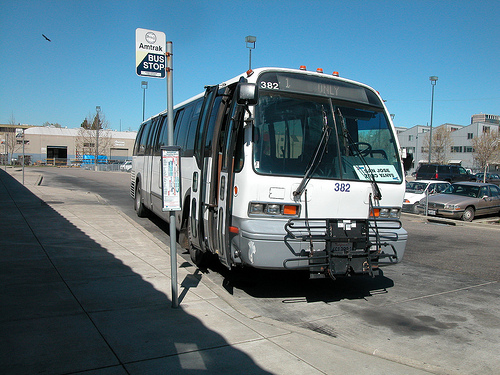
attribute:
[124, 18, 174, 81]
sign — black, white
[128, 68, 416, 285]
bus — white, parked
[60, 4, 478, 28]
sky — blue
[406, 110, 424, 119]
clouds — white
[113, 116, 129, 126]
clouds — white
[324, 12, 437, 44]
sky — blue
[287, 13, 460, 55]
sky — blue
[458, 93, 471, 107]
clouds — white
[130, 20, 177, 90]
sign — black, white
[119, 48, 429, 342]
transit bus — white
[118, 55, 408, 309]
bus — white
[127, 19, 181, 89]
sign — white, blue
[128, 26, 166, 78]
sign — rectangular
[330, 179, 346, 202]
number — black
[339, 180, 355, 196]
number — black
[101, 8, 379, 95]
sky — blue, clear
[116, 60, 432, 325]
bus — long, white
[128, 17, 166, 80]
sign — blue, white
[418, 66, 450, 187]
street lamp — tall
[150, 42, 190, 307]
pole — gray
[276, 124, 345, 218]
windshield wiper — black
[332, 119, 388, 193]
windshield wiper — black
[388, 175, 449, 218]
car — white